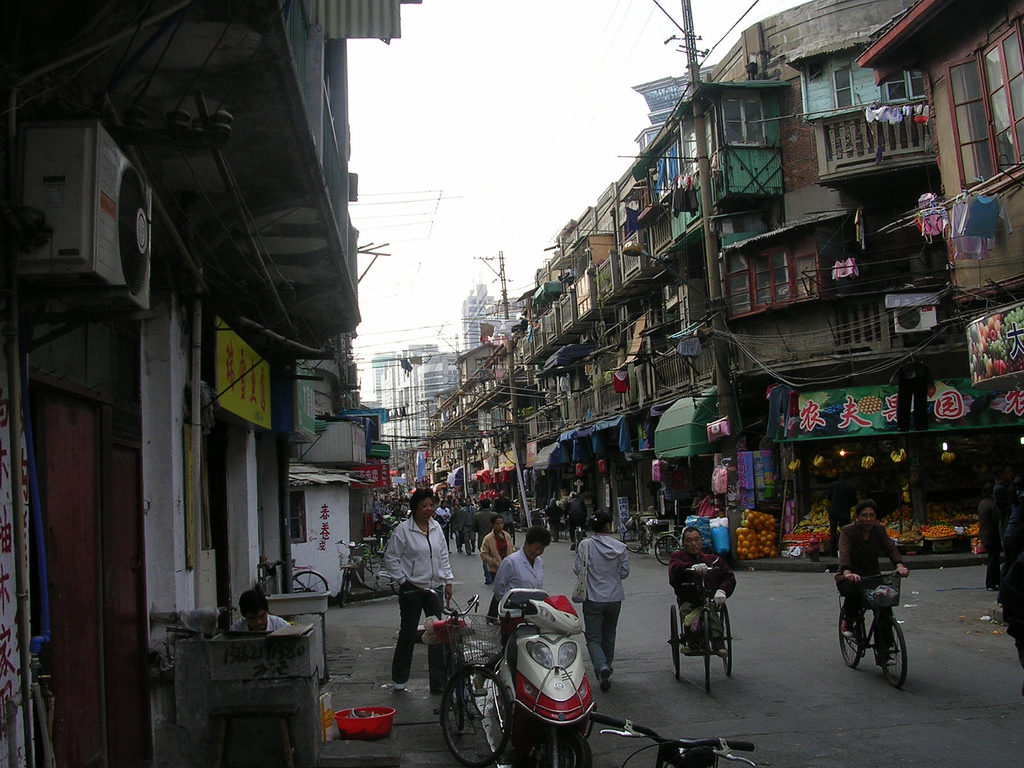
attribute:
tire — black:
[426, 655, 522, 759]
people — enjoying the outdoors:
[86, 353, 633, 602]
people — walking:
[349, 487, 825, 609]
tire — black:
[822, 588, 911, 638]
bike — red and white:
[493, 594, 623, 748]